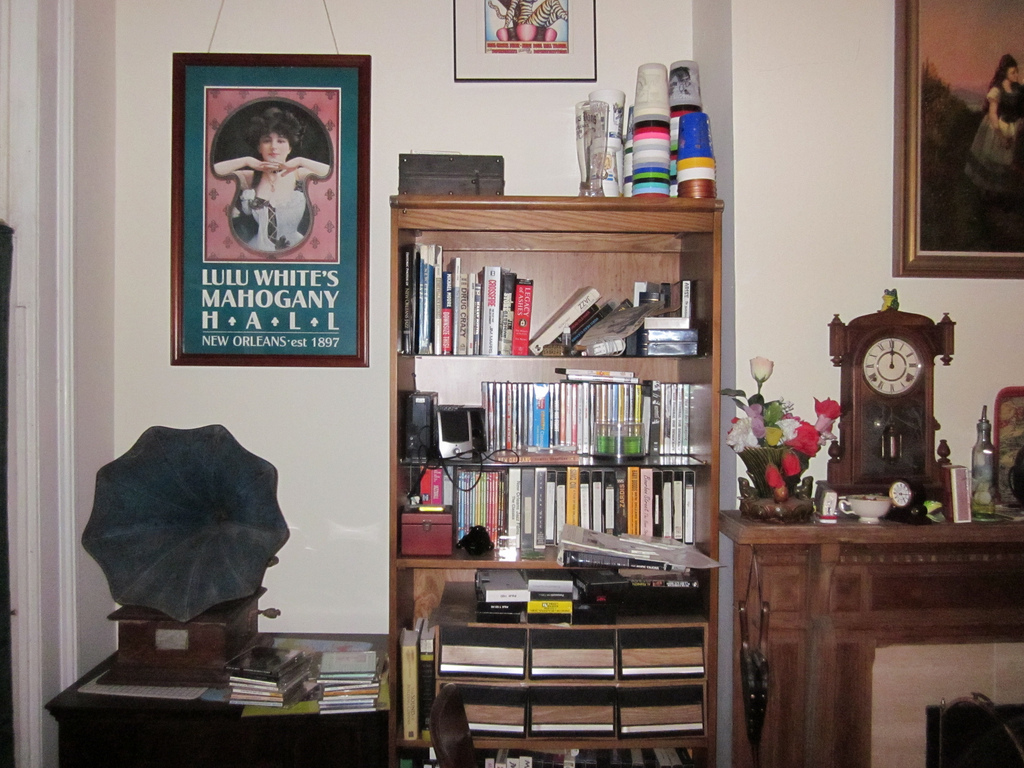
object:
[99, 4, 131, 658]
corner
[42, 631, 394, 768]
end table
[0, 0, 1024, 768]
room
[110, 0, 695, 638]
wall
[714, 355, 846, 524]
floral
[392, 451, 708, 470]
shelf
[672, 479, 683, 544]
book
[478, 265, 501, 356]
book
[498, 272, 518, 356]
book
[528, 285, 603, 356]
book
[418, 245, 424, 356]
book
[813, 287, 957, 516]
clock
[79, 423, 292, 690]
phonograph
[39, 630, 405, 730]
shelf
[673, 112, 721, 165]
cups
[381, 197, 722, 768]
wooden bookcase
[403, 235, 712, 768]
miscellaneous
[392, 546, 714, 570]
shelf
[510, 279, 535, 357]
book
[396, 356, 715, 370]
shelf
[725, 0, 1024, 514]
wall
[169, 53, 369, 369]
antique art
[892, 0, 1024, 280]
antique art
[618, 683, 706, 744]
cd cases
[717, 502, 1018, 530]
mantle